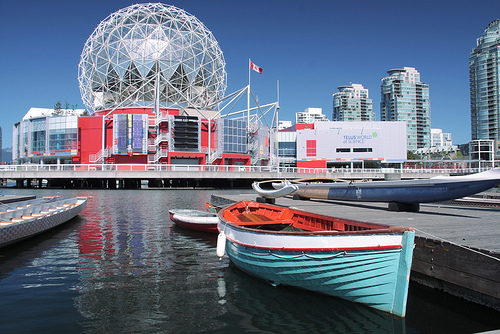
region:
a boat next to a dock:
[194, 193, 426, 332]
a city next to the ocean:
[0, 5, 499, 332]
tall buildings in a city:
[313, 33, 498, 160]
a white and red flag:
[238, 48, 268, 100]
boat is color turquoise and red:
[211, 193, 425, 320]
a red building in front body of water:
[67, 107, 260, 179]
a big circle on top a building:
[73, 5, 232, 116]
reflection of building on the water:
[74, 180, 174, 293]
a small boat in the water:
[160, 193, 217, 242]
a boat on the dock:
[283, 158, 496, 225]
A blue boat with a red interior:
[205, 196, 422, 328]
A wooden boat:
[205, 193, 425, 330]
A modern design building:
[6, 4, 411, 187]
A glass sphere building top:
[70, 4, 237, 116]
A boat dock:
[162, 176, 495, 328]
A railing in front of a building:
[3, 158, 497, 188]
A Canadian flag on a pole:
[239, 50, 269, 168]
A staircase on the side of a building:
[138, 109, 180, 169]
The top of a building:
[372, 54, 437, 93]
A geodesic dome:
[70, 3, 237, 117]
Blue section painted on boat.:
[230, 240, 421, 332]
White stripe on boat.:
[223, 211, 404, 258]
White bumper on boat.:
[198, 229, 255, 268]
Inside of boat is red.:
[251, 208, 336, 243]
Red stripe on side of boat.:
[232, 240, 374, 258]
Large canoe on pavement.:
[301, 162, 447, 209]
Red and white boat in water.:
[169, 203, 217, 233]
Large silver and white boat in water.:
[10, 193, 100, 232]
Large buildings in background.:
[333, 23, 497, 171]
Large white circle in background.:
[73, 11, 279, 92]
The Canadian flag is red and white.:
[240, 45, 270, 170]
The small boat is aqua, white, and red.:
[206, 186, 418, 322]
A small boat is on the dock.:
[271, 156, 493, 206]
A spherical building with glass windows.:
[70, 1, 226, 106]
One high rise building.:
[323, 75, 376, 120]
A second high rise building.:
[375, 60, 430, 150]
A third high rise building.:
[463, 15, 498, 152]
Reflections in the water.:
[57, 215, 167, 315]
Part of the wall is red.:
[80, 121, 96, 149]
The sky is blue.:
[15, 7, 75, 82]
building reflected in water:
[77, 188, 172, 295]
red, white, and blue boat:
[215, 195, 413, 307]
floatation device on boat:
[214, 228, 224, 263]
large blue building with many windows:
[383, 63, 430, 159]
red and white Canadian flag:
[247, 57, 264, 78]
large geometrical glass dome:
[68, 0, 230, 108]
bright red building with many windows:
[78, 115, 245, 171]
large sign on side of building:
[332, 133, 382, 147]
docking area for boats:
[240, 188, 498, 278]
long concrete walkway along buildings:
[10, 160, 429, 180]